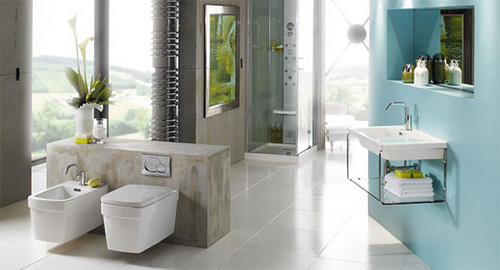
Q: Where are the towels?
A: Under the sink.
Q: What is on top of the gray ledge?
A: Plant.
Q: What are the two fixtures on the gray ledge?
A: Toilet, bidet.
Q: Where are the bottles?
A: Above the sink.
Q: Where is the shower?
A: In the corner.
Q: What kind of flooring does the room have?
A: Tile.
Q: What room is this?
A: Bathroom.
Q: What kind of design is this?
A: Modern.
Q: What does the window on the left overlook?
A: Field, hill.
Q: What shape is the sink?
A: Rectangle.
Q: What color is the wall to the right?
A: Blue.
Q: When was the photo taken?
A: Daytime.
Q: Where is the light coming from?
A: Windows.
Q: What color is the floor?
A: White.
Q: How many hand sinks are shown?
A: ONe.